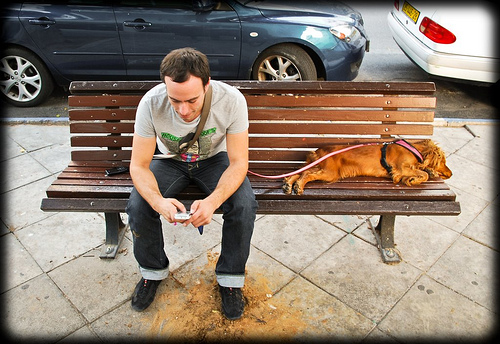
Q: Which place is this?
A: It is a sidewalk.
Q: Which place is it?
A: It is a sidewalk.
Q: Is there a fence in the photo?
A: No, there are no fences.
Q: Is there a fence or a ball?
A: No, there are no fences or balls.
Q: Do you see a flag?
A: No, there are no flags.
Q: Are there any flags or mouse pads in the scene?
A: No, there are no flags or mouse pads.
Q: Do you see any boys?
A: No, there are no boys.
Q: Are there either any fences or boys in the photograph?
A: No, there are no boys or fences.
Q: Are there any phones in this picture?
A: Yes, there is a phone.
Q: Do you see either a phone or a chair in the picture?
A: Yes, there is a phone.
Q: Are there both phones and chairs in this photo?
A: No, there is a phone but no chairs.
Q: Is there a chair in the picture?
A: No, there are no chairs.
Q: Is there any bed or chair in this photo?
A: No, there are no chairs or beds.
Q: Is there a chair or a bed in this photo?
A: No, there are no chairs or beds.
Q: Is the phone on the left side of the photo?
A: Yes, the phone is on the left of the image.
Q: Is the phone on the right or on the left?
A: The phone is on the left of the image.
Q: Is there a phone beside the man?
A: Yes, there is a phone beside the man.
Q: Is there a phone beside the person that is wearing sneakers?
A: Yes, there is a phone beside the man.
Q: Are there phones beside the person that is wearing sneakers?
A: Yes, there is a phone beside the man.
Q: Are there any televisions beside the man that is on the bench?
A: No, there is a phone beside the man.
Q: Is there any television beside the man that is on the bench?
A: No, there is a phone beside the man.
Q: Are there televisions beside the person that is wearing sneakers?
A: No, there is a phone beside the man.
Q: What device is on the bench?
A: The device is a phone.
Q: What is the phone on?
A: The phone is on the bench.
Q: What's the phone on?
A: The phone is on the bench.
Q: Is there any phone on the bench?
A: Yes, there is a phone on the bench.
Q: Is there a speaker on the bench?
A: No, there is a phone on the bench.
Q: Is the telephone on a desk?
A: No, the telephone is on the bench.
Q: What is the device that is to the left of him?
A: The device is a phone.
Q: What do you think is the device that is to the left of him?
A: The device is a phone.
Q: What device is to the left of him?
A: The device is a phone.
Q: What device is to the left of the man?
A: The device is a phone.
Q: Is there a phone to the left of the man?
A: Yes, there is a phone to the left of the man.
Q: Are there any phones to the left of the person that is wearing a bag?
A: Yes, there is a phone to the left of the man.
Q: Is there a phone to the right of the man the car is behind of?
A: No, the phone is to the left of the man.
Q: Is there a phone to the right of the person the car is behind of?
A: No, the phone is to the left of the man.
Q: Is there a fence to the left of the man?
A: No, there is a phone to the left of the man.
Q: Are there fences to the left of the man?
A: No, there is a phone to the left of the man.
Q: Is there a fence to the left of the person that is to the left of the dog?
A: No, there is a phone to the left of the man.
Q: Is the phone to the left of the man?
A: Yes, the phone is to the left of the man.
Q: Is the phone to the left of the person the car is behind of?
A: Yes, the phone is to the left of the man.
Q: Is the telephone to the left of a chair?
A: No, the telephone is to the left of the man.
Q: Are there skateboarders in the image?
A: No, there are no skateboarders.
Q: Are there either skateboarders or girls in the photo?
A: No, there are no skateboarders or girls.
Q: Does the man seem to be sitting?
A: Yes, the man is sitting.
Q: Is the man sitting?
A: Yes, the man is sitting.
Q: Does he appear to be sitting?
A: Yes, the man is sitting.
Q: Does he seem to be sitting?
A: Yes, the man is sitting.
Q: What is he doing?
A: The man is sitting.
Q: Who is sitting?
A: The man is sitting.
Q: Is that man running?
A: No, the man is sitting.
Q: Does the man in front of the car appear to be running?
A: No, the man is sitting.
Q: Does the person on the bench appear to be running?
A: No, the man is sitting.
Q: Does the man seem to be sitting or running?
A: The man is sitting.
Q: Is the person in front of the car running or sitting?
A: The man is sitting.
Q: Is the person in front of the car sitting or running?
A: The man is sitting.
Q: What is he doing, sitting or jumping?
A: The man is sitting.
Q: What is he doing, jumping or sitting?
A: The man is sitting.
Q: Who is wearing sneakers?
A: The man is wearing sneakers.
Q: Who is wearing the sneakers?
A: The man is wearing sneakers.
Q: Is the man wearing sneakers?
A: Yes, the man is wearing sneakers.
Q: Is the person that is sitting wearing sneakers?
A: Yes, the man is wearing sneakers.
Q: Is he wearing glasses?
A: No, the man is wearing sneakers.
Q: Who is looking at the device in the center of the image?
A: The man is looking at the cell phone.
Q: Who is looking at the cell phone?
A: The man is looking at the cell phone.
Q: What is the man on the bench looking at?
A: The man is looking at the cell phone.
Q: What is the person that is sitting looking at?
A: The man is looking at the cell phone.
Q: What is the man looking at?
A: The man is looking at the cell phone.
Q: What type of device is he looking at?
A: The man is looking at the mobile phone.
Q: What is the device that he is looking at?
A: The device is a cell phone.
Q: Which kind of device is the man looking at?
A: The man is looking at the mobile phone.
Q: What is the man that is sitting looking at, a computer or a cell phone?
A: The man is looking at a cell phone.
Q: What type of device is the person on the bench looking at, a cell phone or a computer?
A: The man is looking at a cell phone.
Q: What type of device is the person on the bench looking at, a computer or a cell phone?
A: The man is looking at a cell phone.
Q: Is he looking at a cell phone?
A: Yes, the man is looking at a cell phone.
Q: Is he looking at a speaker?
A: No, the man is looking at a cell phone.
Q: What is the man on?
A: The man is on the bench.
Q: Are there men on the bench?
A: Yes, there is a man on the bench.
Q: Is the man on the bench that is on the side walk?
A: Yes, the man is on the bench.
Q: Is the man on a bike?
A: No, the man is on the bench.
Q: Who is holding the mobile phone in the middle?
A: The man is holding the mobile phone.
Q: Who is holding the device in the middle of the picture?
A: The man is holding the mobile phone.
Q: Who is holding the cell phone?
A: The man is holding the mobile phone.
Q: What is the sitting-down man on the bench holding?
A: The man is holding the cellphone.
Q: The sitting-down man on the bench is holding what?
A: The man is holding the cellphone.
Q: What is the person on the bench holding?
A: The man is holding the cellphone.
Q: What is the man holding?
A: The man is holding the cellphone.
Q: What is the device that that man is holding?
A: The device is a cell phone.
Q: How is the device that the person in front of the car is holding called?
A: The device is a cell phone.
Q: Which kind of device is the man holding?
A: The man is holding the mobile phone.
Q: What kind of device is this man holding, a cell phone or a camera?
A: The man is holding a cell phone.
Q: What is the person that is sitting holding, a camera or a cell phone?
A: The man is holding a cell phone.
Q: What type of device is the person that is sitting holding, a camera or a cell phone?
A: The man is holding a cell phone.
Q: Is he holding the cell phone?
A: Yes, the man is holding the cell phone.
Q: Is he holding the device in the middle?
A: Yes, the man is holding the cell phone.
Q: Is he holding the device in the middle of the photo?
A: Yes, the man is holding the cell phone.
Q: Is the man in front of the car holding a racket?
A: No, the man is holding the cell phone.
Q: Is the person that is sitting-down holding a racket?
A: No, the man is holding the cell phone.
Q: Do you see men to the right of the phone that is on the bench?
A: Yes, there is a man to the right of the phone.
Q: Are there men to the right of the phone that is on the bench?
A: Yes, there is a man to the right of the phone.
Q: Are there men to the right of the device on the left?
A: Yes, there is a man to the right of the phone.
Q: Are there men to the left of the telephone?
A: No, the man is to the right of the telephone.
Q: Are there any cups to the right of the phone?
A: No, there is a man to the right of the phone.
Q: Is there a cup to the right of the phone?
A: No, there is a man to the right of the phone.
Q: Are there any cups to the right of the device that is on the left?
A: No, there is a man to the right of the phone.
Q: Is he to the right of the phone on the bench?
A: Yes, the man is to the right of the phone.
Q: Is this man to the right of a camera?
A: No, the man is to the right of the phone.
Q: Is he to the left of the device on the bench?
A: No, the man is to the right of the phone.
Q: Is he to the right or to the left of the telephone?
A: The man is to the right of the telephone.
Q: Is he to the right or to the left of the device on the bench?
A: The man is to the right of the telephone.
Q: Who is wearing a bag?
A: The man is wearing a bag.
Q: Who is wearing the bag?
A: The man is wearing a bag.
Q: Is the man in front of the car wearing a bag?
A: Yes, the man is wearing a bag.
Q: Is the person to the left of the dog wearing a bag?
A: Yes, the man is wearing a bag.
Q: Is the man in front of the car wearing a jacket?
A: No, the man is wearing a bag.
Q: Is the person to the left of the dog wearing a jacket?
A: No, the man is wearing a bag.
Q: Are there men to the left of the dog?
A: Yes, there is a man to the left of the dog.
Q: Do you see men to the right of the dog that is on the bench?
A: No, the man is to the left of the dog.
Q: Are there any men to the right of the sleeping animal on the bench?
A: No, the man is to the left of the dog.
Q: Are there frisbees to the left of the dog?
A: No, there is a man to the left of the dog.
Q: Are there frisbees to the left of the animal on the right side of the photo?
A: No, there is a man to the left of the dog.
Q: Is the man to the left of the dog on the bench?
A: Yes, the man is to the left of the dog.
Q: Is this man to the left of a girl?
A: No, the man is to the left of the dog.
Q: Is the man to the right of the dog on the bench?
A: No, the man is to the left of the dog.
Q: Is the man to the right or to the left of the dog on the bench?
A: The man is to the left of the dog.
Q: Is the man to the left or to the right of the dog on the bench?
A: The man is to the left of the dog.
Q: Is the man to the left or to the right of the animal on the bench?
A: The man is to the left of the dog.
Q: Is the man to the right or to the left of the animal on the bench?
A: The man is to the left of the dog.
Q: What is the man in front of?
A: The man is in front of the car.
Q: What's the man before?
A: The man is in front of the car.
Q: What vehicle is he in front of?
A: The man is in front of the car.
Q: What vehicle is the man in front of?
A: The man is in front of the car.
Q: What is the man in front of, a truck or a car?
A: The man is in front of a car.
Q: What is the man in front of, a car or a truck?
A: The man is in front of a car.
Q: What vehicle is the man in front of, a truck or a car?
A: The man is in front of a car.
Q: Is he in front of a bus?
A: No, the man is in front of the car.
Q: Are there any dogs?
A: Yes, there is a dog.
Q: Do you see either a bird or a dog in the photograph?
A: Yes, there is a dog.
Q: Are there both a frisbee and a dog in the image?
A: No, there is a dog but no frisbees.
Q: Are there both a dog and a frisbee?
A: No, there is a dog but no frisbees.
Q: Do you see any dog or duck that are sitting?
A: Yes, the dog is sitting.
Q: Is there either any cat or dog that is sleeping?
A: Yes, the dog is sleeping.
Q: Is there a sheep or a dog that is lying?
A: Yes, the dog is lying.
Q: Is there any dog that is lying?
A: Yes, there is a dog that is lying.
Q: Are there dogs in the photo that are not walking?
A: Yes, there is a dog that is lying.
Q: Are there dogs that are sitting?
A: Yes, there is a dog that is sitting.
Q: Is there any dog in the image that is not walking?
A: Yes, there is a dog that is sitting.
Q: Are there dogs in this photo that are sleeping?
A: Yes, there is a dog that is sleeping.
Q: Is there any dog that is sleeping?
A: Yes, there is a dog that is sleeping.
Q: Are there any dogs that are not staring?
A: Yes, there is a dog that is sleeping.